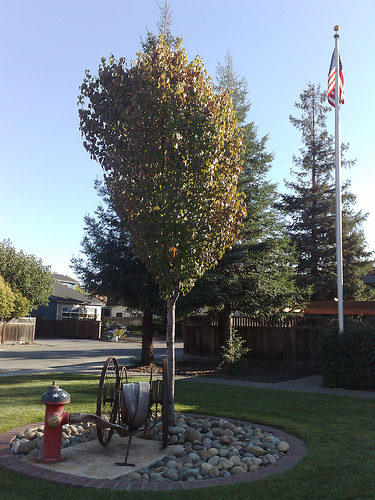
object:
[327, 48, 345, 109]
flag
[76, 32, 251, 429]
tree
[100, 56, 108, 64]
leaf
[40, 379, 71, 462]
hydrant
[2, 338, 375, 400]
pavement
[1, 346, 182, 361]
shadow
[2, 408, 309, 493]
circle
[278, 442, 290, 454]
rock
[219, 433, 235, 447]
rock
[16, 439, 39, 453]
rock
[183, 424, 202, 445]
rock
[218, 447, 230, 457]
rock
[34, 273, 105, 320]
house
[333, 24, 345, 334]
post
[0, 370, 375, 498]
grass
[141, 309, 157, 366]
trunk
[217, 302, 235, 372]
trunk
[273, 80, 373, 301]
pine tree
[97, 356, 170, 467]
hose  organizer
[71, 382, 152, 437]
hose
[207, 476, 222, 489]
brick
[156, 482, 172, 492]
brick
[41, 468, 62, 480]
brick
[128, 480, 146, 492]
brick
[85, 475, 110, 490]
brick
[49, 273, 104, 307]
roof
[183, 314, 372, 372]
fence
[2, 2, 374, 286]
sky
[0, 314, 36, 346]
fence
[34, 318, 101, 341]
fence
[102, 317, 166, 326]
fence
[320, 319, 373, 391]
bush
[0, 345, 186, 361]
road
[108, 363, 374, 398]
walkway